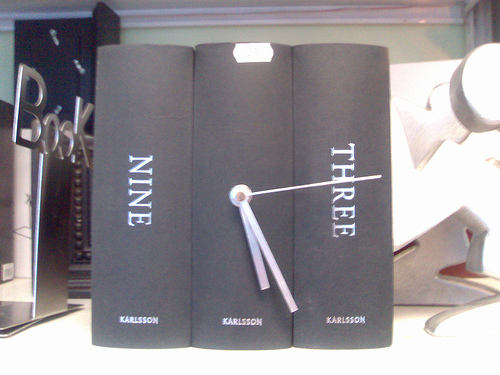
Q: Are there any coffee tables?
A: No, there are no coffee tables.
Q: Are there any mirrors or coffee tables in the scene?
A: No, there are no coffee tables or mirrors.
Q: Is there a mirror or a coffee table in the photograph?
A: No, there are no coffee tables or mirrors.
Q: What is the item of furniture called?
A: The piece of furniture is a shelf.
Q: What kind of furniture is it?
A: The piece of furniture is a shelf.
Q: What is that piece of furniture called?
A: This is a shelf.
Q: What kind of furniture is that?
A: This is a shelf.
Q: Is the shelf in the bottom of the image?
A: Yes, the shelf is in the bottom of the image.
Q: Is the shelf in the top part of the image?
A: No, the shelf is in the bottom of the image.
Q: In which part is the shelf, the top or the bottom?
A: The shelf is in the bottom of the image.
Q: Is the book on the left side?
A: Yes, the book is on the left of the image.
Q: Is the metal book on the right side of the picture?
A: No, the book is on the left of the image.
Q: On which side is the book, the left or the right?
A: The book is on the left of the image.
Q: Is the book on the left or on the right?
A: The book is on the left of the image.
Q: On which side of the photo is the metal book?
A: The book is on the left of the image.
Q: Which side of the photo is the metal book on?
A: The book is on the left of the image.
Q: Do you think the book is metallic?
A: Yes, the book is metallic.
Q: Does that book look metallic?
A: Yes, the book is metallic.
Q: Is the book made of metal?
A: Yes, the book is made of metal.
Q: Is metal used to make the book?
A: Yes, the book is made of metal.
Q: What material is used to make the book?
A: The book is made of metal.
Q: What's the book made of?
A: The book is made of metal.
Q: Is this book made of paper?
A: No, the book is made of metal.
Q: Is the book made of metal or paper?
A: The book is made of metal.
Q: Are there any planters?
A: No, there are no planters.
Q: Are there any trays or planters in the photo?
A: No, there are no planters or trays.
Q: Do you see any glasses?
A: No, there are no glasses.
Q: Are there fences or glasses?
A: No, there are no glasses or fences.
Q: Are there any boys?
A: No, there are no boys.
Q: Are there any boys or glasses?
A: No, there are no boys or glasses.